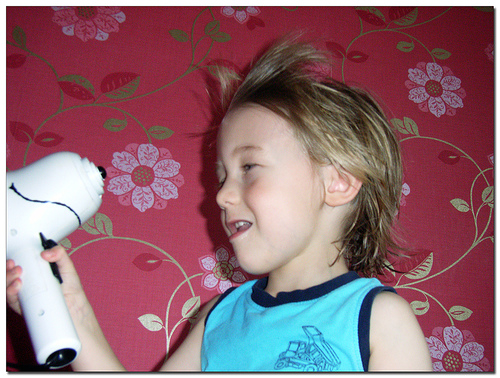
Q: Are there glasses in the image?
A: No, there are no glasses.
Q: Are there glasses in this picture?
A: No, there are no glasses.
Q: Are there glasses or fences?
A: No, there are no glasses or fences.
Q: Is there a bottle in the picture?
A: No, there are no bottles.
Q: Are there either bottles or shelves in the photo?
A: No, there are no bottles or shelves.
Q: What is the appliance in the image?
A: The appliance is a dryer.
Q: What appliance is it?
A: The appliance is a dryer.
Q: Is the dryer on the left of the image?
A: Yes, the dryer is on the left of the image.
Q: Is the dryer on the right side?
A: No, the dryer is on the left of the image.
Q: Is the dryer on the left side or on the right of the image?
A: The dryer is on the left of the image.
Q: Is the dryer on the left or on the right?
A: The dryer is on the left of the image.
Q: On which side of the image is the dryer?
A: The dryer is on the left of the image.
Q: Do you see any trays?
A: No, there are no trays.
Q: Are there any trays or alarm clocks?
A: No, there are no trays or alarm clocks.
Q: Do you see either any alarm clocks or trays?
A: No, there are no trays or alarm clocks.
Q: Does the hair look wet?
A: Yes, the hair is wet.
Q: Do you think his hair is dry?
A: No, the hair is wet.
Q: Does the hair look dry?
A: No, the hair is wet.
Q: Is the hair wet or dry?
A: The hair is wet.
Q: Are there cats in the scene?
A: No, there are no cats.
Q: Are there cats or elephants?
A: No, there are no cats or elephants.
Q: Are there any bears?
A: No, there are no bears.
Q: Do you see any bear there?
A: No, there are no bears.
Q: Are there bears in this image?
A: No, there are no bears.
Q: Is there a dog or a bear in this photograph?
A: No, there are no bears or dogs.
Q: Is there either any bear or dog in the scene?
A: No, there are no bears or dogs.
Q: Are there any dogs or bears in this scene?
A: No, there are no bears or dogs.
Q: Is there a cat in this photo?
A: No, there are no cats.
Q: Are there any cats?
A: No, there are no cats.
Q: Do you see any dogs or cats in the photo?
A: No, there are no cats or dogs.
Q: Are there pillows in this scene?
A: No, there are no pillows.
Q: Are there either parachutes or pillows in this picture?
A: No, there are no pillows or parachutes.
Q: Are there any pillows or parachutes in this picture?
A: No, there are no pillows or parachutes.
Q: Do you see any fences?
A: No, there are no fences.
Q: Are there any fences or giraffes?
A: No, there are no fences or giraffes.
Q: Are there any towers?
A: No, there are no towers.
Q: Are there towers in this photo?
A: No, there are no towers.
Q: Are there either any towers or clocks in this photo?
A: No, there are no towers or clocks.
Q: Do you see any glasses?
A: No, there are no glasses.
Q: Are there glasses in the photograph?
A: No, there are no glasses.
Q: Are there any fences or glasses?
A: No, there are no glasses or fences.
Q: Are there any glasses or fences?
A: No, there are no glasses or fences.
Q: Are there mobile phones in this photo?
A: No, there are no mobile phones.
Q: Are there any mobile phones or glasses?
A: No, there are no mobile phones or glasses.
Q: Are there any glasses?
A: No, there are no glasses.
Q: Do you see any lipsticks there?
A: No, there are no lipsticks.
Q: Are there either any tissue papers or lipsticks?
A: No, there are no lipsticks or tissue papers.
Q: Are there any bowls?
A: No, there are no bowls.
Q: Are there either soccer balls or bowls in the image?
A: No, there are no bowls or soccer balls.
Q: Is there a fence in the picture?
A: No, there are no fences.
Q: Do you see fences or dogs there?
A: No, there are no fences or dogs.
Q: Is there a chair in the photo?
A: No, there are no chairs.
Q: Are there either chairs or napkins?
A: No, there are no chairs or napkins.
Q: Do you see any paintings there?
A: No, there are no paintings.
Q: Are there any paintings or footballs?
A: No, there are no paintings or footballs.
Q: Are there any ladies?
A: No, there are no ladies.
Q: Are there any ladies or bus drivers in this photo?
A: No, there are no ladies or bus drivers.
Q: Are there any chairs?
A: No, there are no chairs.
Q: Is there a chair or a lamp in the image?
A: No, there are no chairs or lamps.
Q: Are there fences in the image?
A: No, there are no fences.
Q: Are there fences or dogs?
A: No, there are no fences or dogs.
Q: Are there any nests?
A: No, there are no nests.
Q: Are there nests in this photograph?
A: No, there are no nests.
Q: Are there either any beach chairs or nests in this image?
A: No, there are no nests or beach chairs.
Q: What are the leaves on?
A: The leaves are on the wall.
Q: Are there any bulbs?
A: No, there are no bulbs.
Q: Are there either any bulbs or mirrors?
A: No, there are no bulbs or mirrors.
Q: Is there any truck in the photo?
A: Yes, there is a truck.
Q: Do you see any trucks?
A: Yes, there is a truck.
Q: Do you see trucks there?
A: Yes, there is a truck.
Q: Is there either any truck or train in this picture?
A: Yes, there is a truck.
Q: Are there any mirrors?
A: No, there are no mirrors.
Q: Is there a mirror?
A: No, there are no mirrors.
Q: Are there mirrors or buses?
A: No, there are no mirrors or buses.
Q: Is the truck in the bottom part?
A: Yes, the truck is in the bottom of the image.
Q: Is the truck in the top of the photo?
A: No, the truck is in the bottom of the image.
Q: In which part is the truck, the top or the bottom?
A: The truck is in the bottom of the image.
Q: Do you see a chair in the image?
A: No, there are no chairs.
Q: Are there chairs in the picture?
A: No, there are no chairs.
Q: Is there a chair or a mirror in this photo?
A: No, there are no chairs or mirrors.